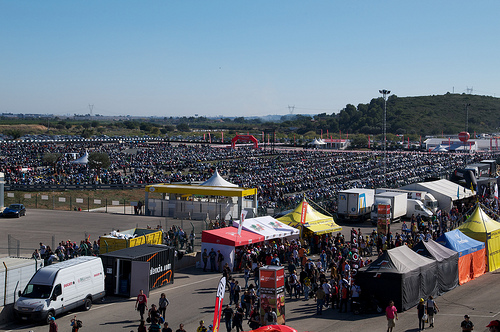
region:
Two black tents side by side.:
[362, 234, 457, 312]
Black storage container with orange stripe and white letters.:
[100, 245, 180, 296]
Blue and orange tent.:
[437, 227, 487, 284]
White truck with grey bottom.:
[16, 251, 113, 321]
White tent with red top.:
[200, 223, 262, 275]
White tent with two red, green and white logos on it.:
[233, 210, 301, 240]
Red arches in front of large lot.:
[227, 130, 257, 152]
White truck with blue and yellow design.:
[335, 180, 375, 215]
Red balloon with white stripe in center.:
[452, 127, 472, 142]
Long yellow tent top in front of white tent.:
[138, 179, 260, 223]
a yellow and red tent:
[278, 197, 335, 231]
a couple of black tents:
[352, 238, 456, 315]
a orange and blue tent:
[439, 223, 489, 293]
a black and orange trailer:
[103, 240, 178, 303]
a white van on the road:
[15, 257, 105, 316]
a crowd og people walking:
[296, 227, 376, 299]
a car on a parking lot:
[2, 202, 27, 223]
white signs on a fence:
[26, 191, 139, 212]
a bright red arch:
[230, 133, 263, 145]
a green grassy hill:
[339, 88, 493, 132]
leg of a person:
[136, 302, 147, 317]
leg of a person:
[237, 315, 249, 330]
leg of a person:
[382, 318, 396, 330]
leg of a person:
[420, 318, 431, 328]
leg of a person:
[425, 311, 445, 324]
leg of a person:
[315, 299, 329, 313]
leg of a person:
[329, 297, 343, 307]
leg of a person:
[294, 287, 303, 299]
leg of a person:
[285, 285, 296, 295]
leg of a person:
[229, 291, 242, 305]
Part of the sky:
[171, 37, 234, 59]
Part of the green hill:
[416, 104, 443, 123]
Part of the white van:
[69, 268, 85, 278]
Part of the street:
[187, 287, 197, 309]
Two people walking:
[414, 292, 441, 330]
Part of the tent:
[397, 254, 419, 278]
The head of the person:
[387, 298, 395, 305]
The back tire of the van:
[81, 296, 95, 311]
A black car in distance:
[1, 200, 28, 222]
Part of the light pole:
[381, 90, 387, 107]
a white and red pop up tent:
[198, 227, 262, 269]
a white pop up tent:
[232, 215, 299, 256]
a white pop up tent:
[403, 176, 475, 211]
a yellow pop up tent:
[454, 205, 499, 274]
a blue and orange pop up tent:
[435, 225, 485, 282]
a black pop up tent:
[410, 238, 457, 293]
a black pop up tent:
[356, 243, 436, 310]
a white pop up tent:
[200, 166, 238, 190]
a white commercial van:
[13, 254, 105, 321]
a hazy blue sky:
[0, 0, 498, 113]